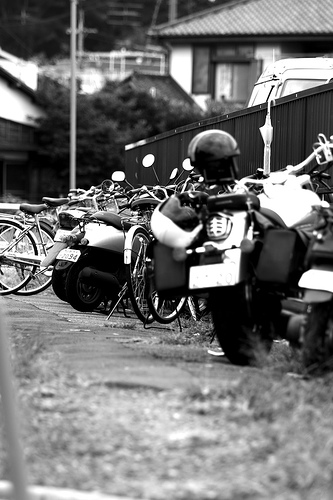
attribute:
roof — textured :
[145, 0, 331, 45]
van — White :
[242, 55, 331, 108]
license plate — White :
[53, 244, 88, 265]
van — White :
[246, 48, 332, 123]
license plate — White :
[55, 244, 84, 263]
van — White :
[247, 54, 328, 108]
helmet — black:
[184, 128, 241, 183]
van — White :
[246, 59, 331, 111]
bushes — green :
[76, 71, 140, 158]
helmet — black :
[191, 125, 241, 185]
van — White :
[234, 46, 328, 127]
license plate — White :
[51, 242, 97, 264]